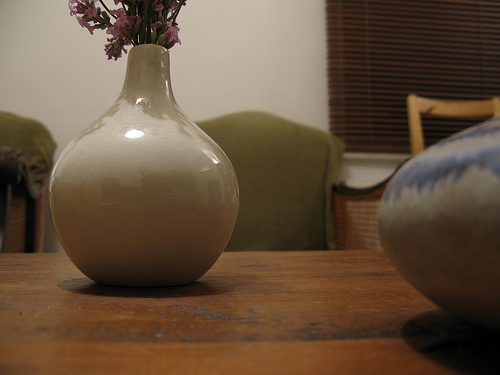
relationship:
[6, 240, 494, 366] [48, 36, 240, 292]
table holds vase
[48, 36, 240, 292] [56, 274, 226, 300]
vase has shadow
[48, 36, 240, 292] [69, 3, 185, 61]
vase holds flowers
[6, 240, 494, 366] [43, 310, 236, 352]
table has grooves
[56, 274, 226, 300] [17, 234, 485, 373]
shadow on table